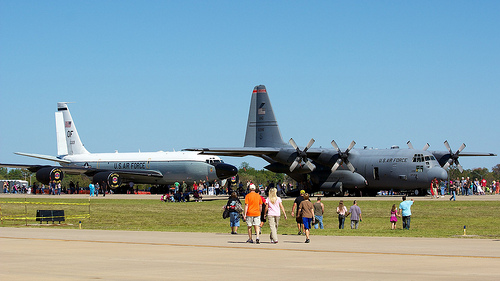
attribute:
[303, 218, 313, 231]
shorts — blue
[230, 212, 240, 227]
shorts — blue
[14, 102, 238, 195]
airplane — large, silver, white, air force, grey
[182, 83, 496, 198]
airplane — large, grey, air force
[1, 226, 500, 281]
tarmac — brown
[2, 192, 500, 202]
tarmac — brown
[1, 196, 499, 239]
grass — green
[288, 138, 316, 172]
propeller — large, grey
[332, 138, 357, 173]
propeller — large, grey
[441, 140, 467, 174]
propeller — large, grey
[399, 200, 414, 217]
t-shirt — light blue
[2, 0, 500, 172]
sky — clear, blue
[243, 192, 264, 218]
t-shirt — orange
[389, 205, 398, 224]
dress — pink